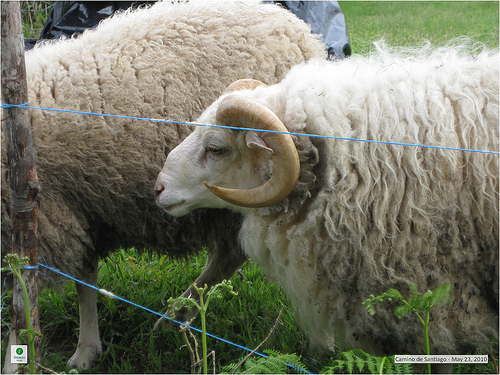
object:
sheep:
[152, 32, 499, 374]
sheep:
[0, 0, 329, 372]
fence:
[0, 0, 499, 375]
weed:
[166, 278, 240, 374]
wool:
[0, 0, 327, 296]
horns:
[204, 96, 301, 208]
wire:
[0, 101, 498, 154]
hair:
[261, 35, 499, 362]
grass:
[104, 263, 149, 361]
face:
[153, 123, 261, 218]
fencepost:
[0, 0, 45, 374]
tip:
[203, 179, 255, 207]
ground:
[0, 250, 305, 373]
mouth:
[153, 195, 190, 217]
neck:
[251, 81, 329, 228]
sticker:
[9, 344, 30, 363]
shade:
[0, 286, 262, 374]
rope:
[7, 261, 313, 374]